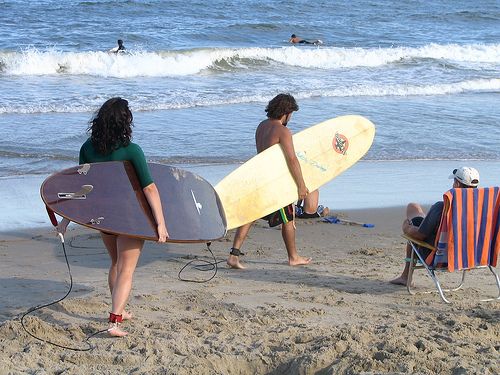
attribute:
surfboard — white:
[213, 112, 375, 229]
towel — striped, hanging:
[446, 187, 498, 271]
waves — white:
[7, 23, 482, 78]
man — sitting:
[391, 164, 478, 288]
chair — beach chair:
[405, 183, 499, 310]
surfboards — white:
[216, 112, 371, 205]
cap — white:
[441, 156, 488, 207]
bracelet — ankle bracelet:
[14, 209, 126, 356]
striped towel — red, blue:
[430, 173, 497, 265]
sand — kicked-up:
[381, 313, 393, 348]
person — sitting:
[387, 164, 480, 287]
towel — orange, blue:
[452, 190, 479, 284]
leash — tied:
[21, 231, 123, 350]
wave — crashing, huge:
[0, 42, 497, 80]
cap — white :
[450, 166, 479, 186]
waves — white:
[56, 20, 487, 120]